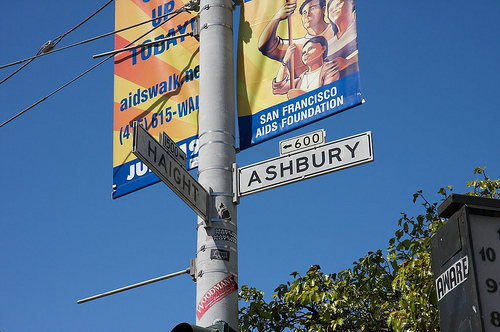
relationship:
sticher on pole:
[193, 270, 245, 322] [188, 1, 244, 330]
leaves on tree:
[322, 271, 372, 314] [235, 169, 438, 330]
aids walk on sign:
[117, 2, 353, 174] [99, 1, 371, 204]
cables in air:
[1, 6, 195, 131] [4, 4, 327, 214]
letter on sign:
[244, 165, 262, 185] [226, 122, 386, 203]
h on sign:
[277, 154, 295, 183] [226, 122, 386, 203]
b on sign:
[293, 153, 313, 174] [228, 122, 377, 200]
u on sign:
[310, 149, 326, 170] [308, 149, 328, 174]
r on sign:
[324, 142, 345, 167] [322, 144, 342, 169]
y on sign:
[342, 138, 362, 158] [233, 127, 380, 203]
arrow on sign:
[281, 139, 293, 153] [230, 121, 377, 193]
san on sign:
[255, 104, 282, 127] [99, 1, 371, 204]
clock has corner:
[468, 204, 495, 329] [417, 183, 498, 330]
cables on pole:
[1, 6, 195, 131] [188, 1, 244, 330]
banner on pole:
[102, 1, 369, 210] [188, 1, 244, 330]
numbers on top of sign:
[159, 123, 194, 172] [128, 117, 215, 217]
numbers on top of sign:
[271, 128, 327, 154] [237, 125, 383, 206]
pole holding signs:
[188, 1, 244, 330] [104, 5, 371, 192]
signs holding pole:
[234, 126, 380, 197] [188, 1, 244, 330]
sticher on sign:
[193, 270, 245, 322] [192, 230, 245, 330]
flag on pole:
[106, 1, 371, 191] [194, 3, 244, 314]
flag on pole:
[108, 5, 387, 187] [194, 3, 244, 314]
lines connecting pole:
[1, 18, 190, 125] [188, 1, 244, 330]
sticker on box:
[431, 251, 468, 301] [428, 196, 484, 301]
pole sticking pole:
[68, 263, 190, 314] [188, 1, 244, 332]